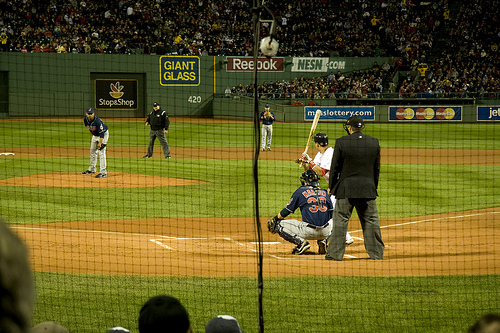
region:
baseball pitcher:
[81, 103, 116, 180]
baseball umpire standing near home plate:
[324, 113, 396, 265]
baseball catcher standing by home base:
[266, 168, 335, 260]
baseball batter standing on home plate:
[296, 108, 353, 244]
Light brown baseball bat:
[296, 108, 321, 168]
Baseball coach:
[142, 100, 177, 162]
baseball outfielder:
[258, 101, 278, 152]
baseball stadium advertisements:
[301, 103, 499, 125]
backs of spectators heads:
[134, 293, 246, 331]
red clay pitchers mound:
[1, 168, 212, 191]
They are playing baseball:
[10, 7, 490, 322]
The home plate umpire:
[333, 112, 392, 252]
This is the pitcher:
[75, 100, 113, 180]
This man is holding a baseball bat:
[298, 103, 338, 178]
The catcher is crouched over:
[242, 168, 339, 255]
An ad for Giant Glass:
[152, 52, 206, 88]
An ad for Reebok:
[222, 49, 283, 73]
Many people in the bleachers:
[27, 4, 494, 102]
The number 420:
[176, 87, 211, 112]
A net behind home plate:
[10, 13, 490, 312]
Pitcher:
[79, 105, 111, 175]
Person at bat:
[299, 110, 352, 245]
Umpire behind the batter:
[323, 118, 387, 258]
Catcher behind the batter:
[265, 171, 345, 257]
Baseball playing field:
[1, 109, 498, 329]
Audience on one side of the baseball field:
[1, 0, 497, 124]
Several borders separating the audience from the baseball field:
[0, 48, 498, 128]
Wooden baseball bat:
[297, 108, 322, 159]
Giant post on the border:
[156, 52, 206, 88]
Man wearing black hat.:
[346, 113, 362, 118]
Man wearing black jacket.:
[335, 152, 377, 174]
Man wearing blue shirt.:
[288, 185, 322, 218]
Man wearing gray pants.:
[281, 215, 313, 232]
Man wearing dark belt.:
[303, 215, 341, 240]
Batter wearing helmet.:
[308, 129, 333, 148]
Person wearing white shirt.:
[305, 150, 335, 163]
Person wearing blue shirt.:
[73, 118, 111, 125]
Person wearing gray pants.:
[72, 135, 121, 150]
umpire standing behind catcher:
[322, 114, 391, 256]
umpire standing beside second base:
[139, 102, 176, 157]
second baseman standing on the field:
[254, 100, 279, 150]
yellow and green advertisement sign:
[157, 53, 202, 88]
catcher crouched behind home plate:
[274, 173, 344, 256]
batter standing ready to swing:
[300, 103, 357, 248]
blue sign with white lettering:
[302, 103, 374, 121]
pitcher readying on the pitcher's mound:
[73, 105, 110, 179]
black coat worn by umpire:
[333, 135, 380, 197]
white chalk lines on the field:
[17, 214, 468, 263]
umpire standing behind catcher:
[315, 104, 390, 266]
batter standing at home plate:
[294, 104, 358, 253]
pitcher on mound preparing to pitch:
[77, 105, 113, 177]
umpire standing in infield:
[136, 99, 174, 164]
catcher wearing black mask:
[293, 164, 324, 185]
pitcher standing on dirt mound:
[0, 105, 215, 188]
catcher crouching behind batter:
[266, 130, 356, 255]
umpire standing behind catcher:
[266, 112, 385, 261]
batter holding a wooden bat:
[294, 108, 354, 243]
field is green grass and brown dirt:
[2, 115, 497, 332]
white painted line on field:
[0, 115, 498, 332]